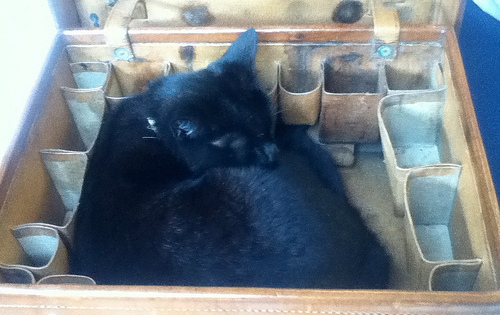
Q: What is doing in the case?
A: Sleeping.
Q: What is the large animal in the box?
A: A cat.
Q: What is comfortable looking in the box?
A: Cat.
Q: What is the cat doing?
A: Laying down.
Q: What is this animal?
A: A cat.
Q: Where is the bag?
A: Around cat.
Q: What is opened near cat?
A: Bag.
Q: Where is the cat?
A: Inside a container.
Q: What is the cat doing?
A: Lying down.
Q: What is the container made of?
A: Leather.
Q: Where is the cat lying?
A: In the suitcase.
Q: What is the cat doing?
A: Lying in the suitcase.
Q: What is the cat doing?
A: Curling up inside of the suit case.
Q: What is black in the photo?
A: Cat.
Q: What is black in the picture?
A: Cat.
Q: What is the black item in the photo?
A: Cat.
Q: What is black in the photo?
A: Cat.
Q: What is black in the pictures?
A: Cat.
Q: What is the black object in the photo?
A: Cat.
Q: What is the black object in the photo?
A: Cat.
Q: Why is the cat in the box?
A: It is sleeping.